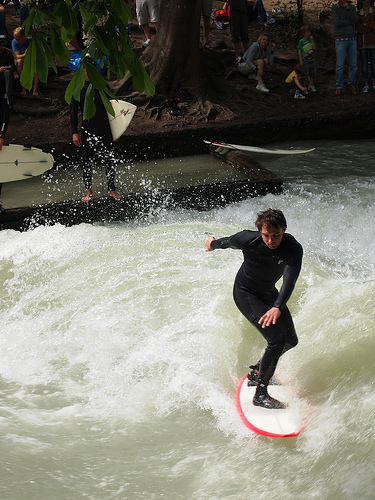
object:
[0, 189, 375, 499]
sea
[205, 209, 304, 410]
man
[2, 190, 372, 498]
wave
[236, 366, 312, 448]
surfboard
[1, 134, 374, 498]
water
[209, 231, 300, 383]
wet suit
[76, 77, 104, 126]
leaf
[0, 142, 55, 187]
surfboard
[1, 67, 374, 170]
ground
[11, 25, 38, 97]
person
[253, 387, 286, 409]
shoe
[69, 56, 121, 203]
person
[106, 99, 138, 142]
surfboard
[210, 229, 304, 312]
rashguard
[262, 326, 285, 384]
legging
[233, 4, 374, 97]
spectator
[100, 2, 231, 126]
trunk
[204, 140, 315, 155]
board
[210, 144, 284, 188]
log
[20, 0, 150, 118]
branch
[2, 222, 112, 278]
foam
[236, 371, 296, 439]
edge